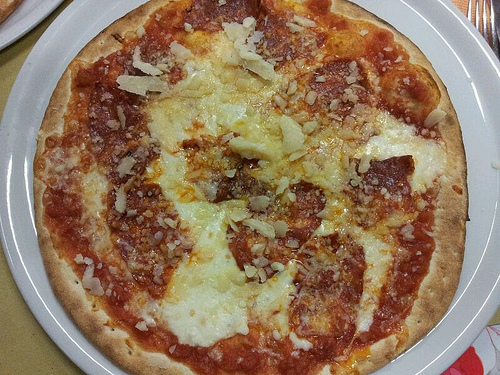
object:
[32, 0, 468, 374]
pizza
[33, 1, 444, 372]
cheese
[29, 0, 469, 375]
crust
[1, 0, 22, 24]
pizza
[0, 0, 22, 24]
crust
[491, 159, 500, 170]
parmesan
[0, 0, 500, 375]
plate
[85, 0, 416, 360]
meat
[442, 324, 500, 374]
napkin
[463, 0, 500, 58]
fork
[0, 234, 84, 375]
tablecloth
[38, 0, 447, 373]
sauce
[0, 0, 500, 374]
tablecloth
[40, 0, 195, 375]
edge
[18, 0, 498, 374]
inside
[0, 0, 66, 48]
plate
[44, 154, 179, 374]
crust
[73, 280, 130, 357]
holes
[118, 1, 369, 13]
topping